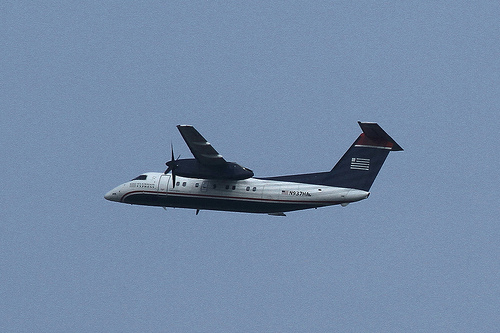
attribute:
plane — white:
[103, 121, 403, 216]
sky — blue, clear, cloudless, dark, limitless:
[1, 2, 500, 332]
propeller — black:
[165, 144, 180, 190]